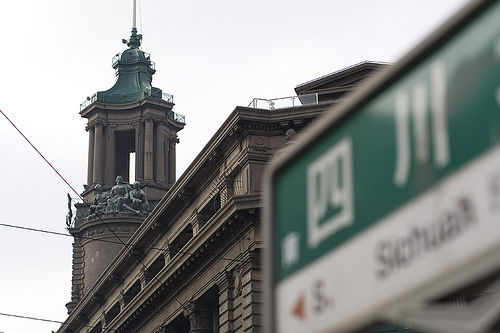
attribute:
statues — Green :
[86, 174, 153, 221]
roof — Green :
[77, 27, 177, 112]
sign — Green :
[260, 1, 498, 331]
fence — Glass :
[243, 91, 323, 110]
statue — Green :
[120, 27, 143, 47]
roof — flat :
[55, 98, 344, 331]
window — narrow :
[89, 319, 101, 330]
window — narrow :
[123, 278, 143, 310]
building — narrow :
[57, 59, 394, 330]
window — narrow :
[145, 250, 165, 282]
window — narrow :
[168, 222, 194, 264]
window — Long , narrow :
[113, 127, 140, 184]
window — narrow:
[189, 285, 225, 330]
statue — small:
[84, 172, 155, 218]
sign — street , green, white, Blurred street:
[273, 6, 479, 331]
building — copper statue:
[36, 11, 471, 321]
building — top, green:
[88, 37, 168, 116]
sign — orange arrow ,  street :
[284, 287, 322, 318]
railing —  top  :
[254, 87, 314, 107]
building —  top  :
[50, 78, 484, 328]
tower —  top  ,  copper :
[64, 4, 200, 114]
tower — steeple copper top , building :
[94, 0, 165, 97]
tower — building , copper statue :
[68, 2, 167, 98]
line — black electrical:
[2, 112, 82, 330]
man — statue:
[81, 174, 161, 227]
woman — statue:
[78, 174, 152, 213]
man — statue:
[91, 161, 140, 205]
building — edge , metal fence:
[64, 10, 461, 329]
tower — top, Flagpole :
[73, 5, 194, 198]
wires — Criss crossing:
[4, 102, 130, 302]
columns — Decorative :
[126, 112, 176, 181]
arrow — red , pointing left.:
[284, 288, 309, 322]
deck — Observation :
[59, 175, 131, 238]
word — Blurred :
[358, 188, 472, 283]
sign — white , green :
[258, 9, 482, 324]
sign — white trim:
[272, 170, 484, 330]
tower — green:
[69, 21, 188, 275]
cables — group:
[67, 70, 187, 324]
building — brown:
[34, 99, 284, 330]